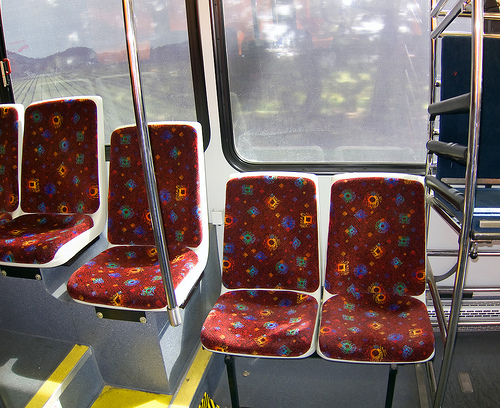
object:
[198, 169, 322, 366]
two seats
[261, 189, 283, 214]
design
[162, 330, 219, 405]
line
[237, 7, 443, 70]
light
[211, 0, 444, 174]
window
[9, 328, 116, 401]
shadow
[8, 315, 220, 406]
floor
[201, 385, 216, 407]
stripes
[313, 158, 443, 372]
three seats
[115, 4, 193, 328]
pole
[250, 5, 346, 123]
trees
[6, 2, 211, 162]
rear window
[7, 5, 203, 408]
left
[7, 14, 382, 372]
center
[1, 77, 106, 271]
elevated seats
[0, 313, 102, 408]
steps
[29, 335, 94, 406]
caution tape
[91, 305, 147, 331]
plate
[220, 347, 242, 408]
legs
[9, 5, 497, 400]
train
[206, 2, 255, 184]
black frame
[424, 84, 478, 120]
three poles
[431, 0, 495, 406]
two poles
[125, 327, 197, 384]
reflection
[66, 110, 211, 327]
seat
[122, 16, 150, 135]
light reflection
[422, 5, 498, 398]
luggage rack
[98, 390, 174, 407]
yellow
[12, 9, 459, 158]
field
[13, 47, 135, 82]
mountain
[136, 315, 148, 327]
bolts